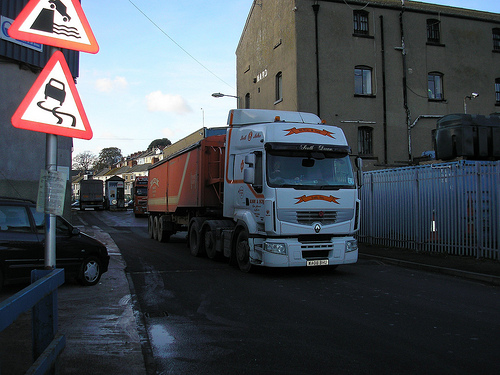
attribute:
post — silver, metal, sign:
[44, 132, 59, 267]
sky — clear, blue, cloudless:
[72, 2, 254, 164]